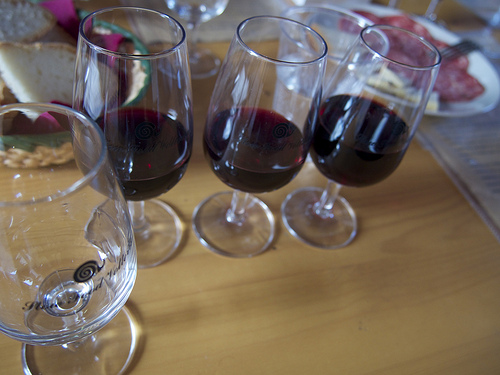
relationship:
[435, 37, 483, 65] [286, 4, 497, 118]
fork on plate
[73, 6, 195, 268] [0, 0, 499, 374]
glass on table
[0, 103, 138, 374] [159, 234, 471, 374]
glass on table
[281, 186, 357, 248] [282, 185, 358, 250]
base of glass base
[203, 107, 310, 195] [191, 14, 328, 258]
wine in glass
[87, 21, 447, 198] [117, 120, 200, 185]
three glasses with dark liquid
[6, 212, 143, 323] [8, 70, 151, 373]
writing on glass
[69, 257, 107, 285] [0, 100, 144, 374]
black design on glass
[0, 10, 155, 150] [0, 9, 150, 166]
trim on basket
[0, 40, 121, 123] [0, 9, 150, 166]
bread on basket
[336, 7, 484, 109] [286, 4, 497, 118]
food on plate